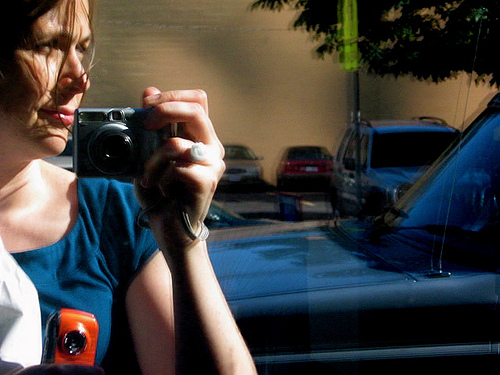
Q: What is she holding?
A: A camera.